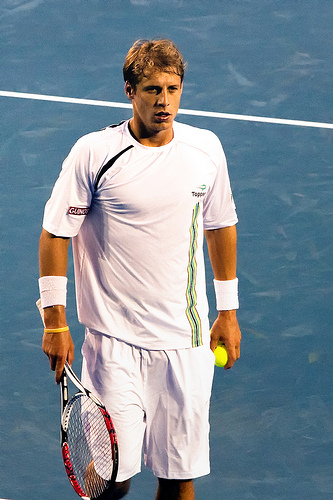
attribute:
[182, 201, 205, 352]
stripes — yellow, maroon, brown, green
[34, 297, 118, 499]
tennis racket — black, red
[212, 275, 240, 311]
wrist band — white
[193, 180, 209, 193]
logo — green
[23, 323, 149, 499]
tennis racket — white, black, red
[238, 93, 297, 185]
court — blue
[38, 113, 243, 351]
shirt — white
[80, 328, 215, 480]
shorts — white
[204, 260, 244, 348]
wrist band — white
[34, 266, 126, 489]
racket — white, red, black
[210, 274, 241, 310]
band — white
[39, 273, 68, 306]
band — white